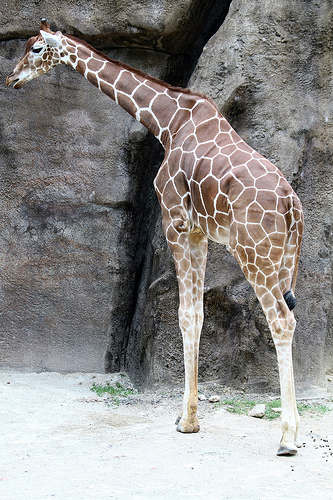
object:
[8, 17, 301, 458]
giraffe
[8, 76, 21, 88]
mouth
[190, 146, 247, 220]
pattern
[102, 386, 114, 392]
grass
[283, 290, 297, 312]
end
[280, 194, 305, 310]
tail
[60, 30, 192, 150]
neck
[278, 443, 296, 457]
hoof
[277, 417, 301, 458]
foot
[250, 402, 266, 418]
rock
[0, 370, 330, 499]
ground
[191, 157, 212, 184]
spot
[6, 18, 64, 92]
head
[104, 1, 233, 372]
crack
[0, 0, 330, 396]
rock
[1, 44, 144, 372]
side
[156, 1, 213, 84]
blackness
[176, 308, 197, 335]
knee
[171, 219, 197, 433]
leg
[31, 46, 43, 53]
eye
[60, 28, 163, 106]
fur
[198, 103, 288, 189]
back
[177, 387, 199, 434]
foot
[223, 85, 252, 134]
opening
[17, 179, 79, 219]
bump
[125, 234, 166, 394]
edge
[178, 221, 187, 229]
opening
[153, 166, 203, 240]
thigh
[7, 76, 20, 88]
lips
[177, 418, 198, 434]
hoof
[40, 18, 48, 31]
horn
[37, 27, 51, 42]
ear